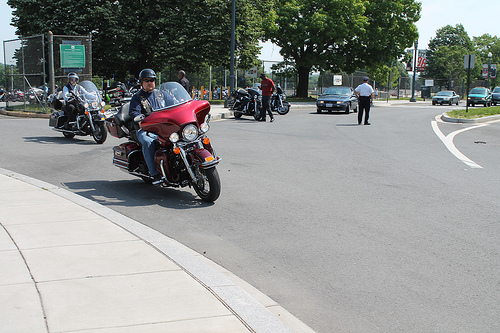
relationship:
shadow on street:
[57, 154, 216, 237] [0, 94, 497, 295]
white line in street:
[429, 120, 445, 141] [0, 97, 499, 332]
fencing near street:
[10, 23, 98, 104] [0, 97, 499, 332]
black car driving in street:
[312, 84, 362, 116] [0, 97, 499, 332]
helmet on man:
[136, 59, 163, 91] [130, 67, 170, 184]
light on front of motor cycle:
[177, 122, 203, 144] [101, 81, 231, 210]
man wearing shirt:
[125, 64, 185, 184] [128, 88, 158, 132]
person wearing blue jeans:
[127, 65, 161, 185] [138, 126, 158, 174]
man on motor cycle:
[125, 64, 185, 184] [101, 81, 231, 210]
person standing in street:
[354, 77, 374, 126] [0, 97, 499, 332]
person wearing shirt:
[257, 72, 277, 124] [258, 77, 275, 97]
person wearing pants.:
[259, 68, 277, 124] [252, 94, 278, 123]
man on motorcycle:
[125, 64, 185, 184] [103, 80, 222, 204]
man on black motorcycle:
[61, 69, 98, 128] [28, 83, 117, 165]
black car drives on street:
[312, 80, 362, 118] [0, 97, 499, 332]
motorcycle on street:
[223, 87, 270, 126] [222, 114, 497, 309]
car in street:
[430, 90, 461, 107] [0, 97, 499, 332]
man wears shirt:
[125, 64, 185, 184] [122, 89, 184, 126]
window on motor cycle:
[143, 83, 193, 110] [101, 93, 231, 210]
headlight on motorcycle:
[181, 124, 201, 143] [103, 80, 222, 204]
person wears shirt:
[354, 76, 374, 126] [351, 83, 375, 98]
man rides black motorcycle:
[63, 69, 96, 121] [42, 79, 110, 145]